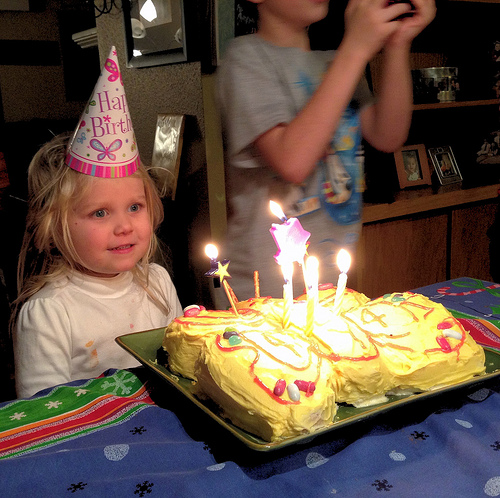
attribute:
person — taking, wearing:
[15, 174, 188, 423]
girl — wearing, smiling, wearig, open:
[14, 132, 182, 430]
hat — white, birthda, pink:
[54, 52, 157, 202]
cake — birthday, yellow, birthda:
[145, 221, 468, 465]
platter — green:
[67, 373, 118, 418]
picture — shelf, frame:
[317, 117, 486, 258]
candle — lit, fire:
[182, 163, 381, 358]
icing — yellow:
[406, 307, 440, 384]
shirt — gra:
[234, 64, 299, 149]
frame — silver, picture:
[417, 112, 466, 187]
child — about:
[53, 112, 188, 304]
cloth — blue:
[110, 414, 144, 465]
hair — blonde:
[20, 188, 80, 278]